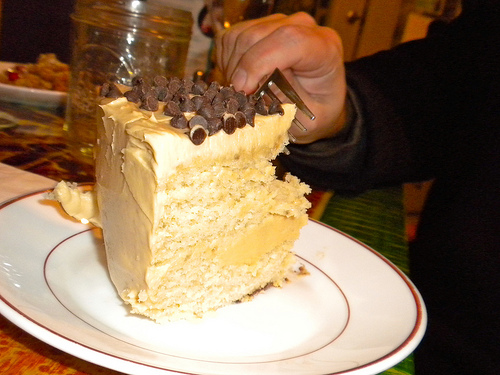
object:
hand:
[211, 10, 353, 146]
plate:
[1, 177, 422, 372]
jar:
[67, 6, 189, 187]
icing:
[76, 89, 177, 305]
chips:
[153, 75, 170, 87]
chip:
[267, 101, 285, 117]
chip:
[190, 82, 207, 95]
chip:
[190, 95, 205, 111]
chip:
[188, 115, 208, 131]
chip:
[221, 113, 238, 135]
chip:
[170, 112, 190, 129]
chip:
[152, 75, 170, 88]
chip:
[139, 94, 159, 112]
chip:
[162, 100, 183, 116]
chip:
[186, 124, 209, 147]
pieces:
[108, 67, 183, 123]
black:
[437, 55, 500, 257]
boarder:
[318, 289, 418, 351]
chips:
[158, 86, 175, 101]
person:
[212, 8, 500, 375]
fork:
[236, 66, 317, 156]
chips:
[182, 123, 208, 146]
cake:
[47, 77, 312, 325]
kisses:
[145, 83, 224, 150]